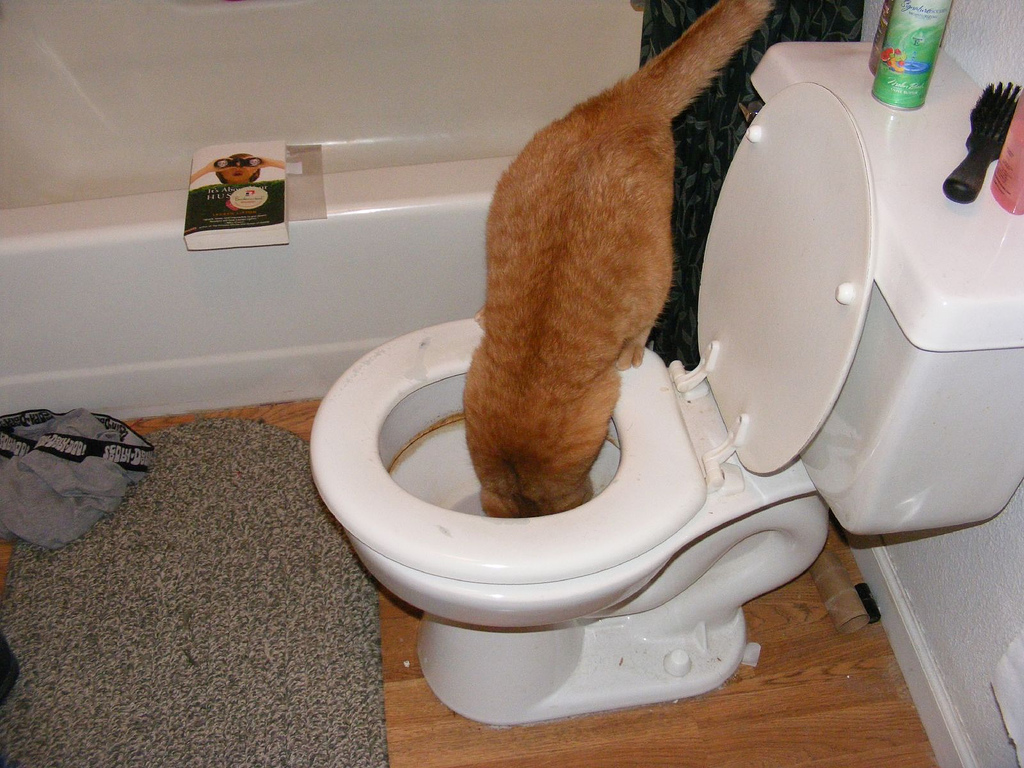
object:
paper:
[988, 638, 1024, 766]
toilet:
[304, 39, 1024, 727]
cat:
[462, 0, 779, 518]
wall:
[844, 495, 1024, 768]